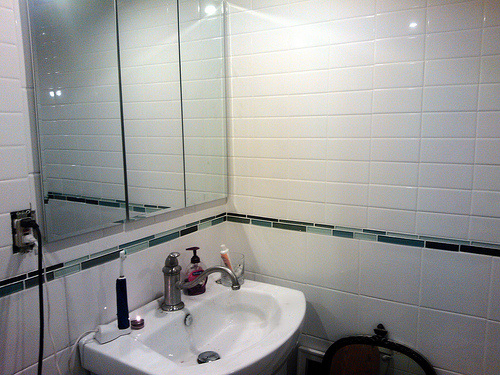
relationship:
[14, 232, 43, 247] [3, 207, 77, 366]
outlet has a white cord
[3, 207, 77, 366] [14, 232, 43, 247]
cord plugged into the outlet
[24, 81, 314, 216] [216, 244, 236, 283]
glass holding tube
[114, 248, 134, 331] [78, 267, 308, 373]
toothbrush on sink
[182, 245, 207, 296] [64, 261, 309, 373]
bottle on sink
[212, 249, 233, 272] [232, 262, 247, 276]
tube in glass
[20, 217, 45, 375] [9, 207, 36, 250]
cord plugged into outlet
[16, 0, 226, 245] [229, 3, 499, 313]
mirror on wall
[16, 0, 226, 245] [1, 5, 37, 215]
mirror on wall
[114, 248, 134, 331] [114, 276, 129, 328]
toothbrush has handle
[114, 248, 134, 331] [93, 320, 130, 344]
toothbrush with base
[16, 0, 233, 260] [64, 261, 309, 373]
mirror over sink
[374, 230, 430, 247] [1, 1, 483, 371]
green tile around bathroom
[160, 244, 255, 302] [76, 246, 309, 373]
faucet on sink